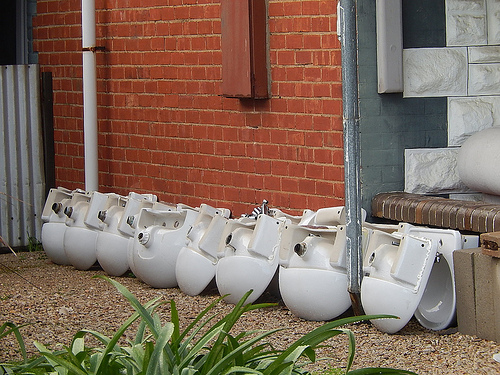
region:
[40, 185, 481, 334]
ceramic sink bowls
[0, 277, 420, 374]
green leaves from a plant in the foreground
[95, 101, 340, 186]
red bricks in a wall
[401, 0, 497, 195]
ceramic molds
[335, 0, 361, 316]
metal drain pipe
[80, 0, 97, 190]
white pvc pipe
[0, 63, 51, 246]
corregated metal sheeting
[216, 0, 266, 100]
weathered red wooden box on the wall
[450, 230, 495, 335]
grey cinder blocks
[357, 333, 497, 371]
gravel covered ground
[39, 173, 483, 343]
a whole lot of sinks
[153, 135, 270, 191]
the wall is made of brick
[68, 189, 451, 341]
the sinks are white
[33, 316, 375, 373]
green plants are growing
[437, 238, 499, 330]
concrete blocks are to the right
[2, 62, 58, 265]
pleated metal fence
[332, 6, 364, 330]
a downspout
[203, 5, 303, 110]
some type of box on the wall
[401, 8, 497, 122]
stone-like blocks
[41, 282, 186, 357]
gravel on the ground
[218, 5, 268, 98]
Rusty red box on side of wall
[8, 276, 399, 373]
Small patch of green grass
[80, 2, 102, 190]
Long white pvc pipe hooked to wall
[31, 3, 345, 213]
Tall brick wall on building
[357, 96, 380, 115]
Small grey brick in wall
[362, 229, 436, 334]
Glass white sink leaning against sink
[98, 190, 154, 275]
White glass sink leaning agains wall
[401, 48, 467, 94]
Large white block in wall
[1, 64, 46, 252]
Small grey metal fencing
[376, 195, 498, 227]
Rusty brick floor on porch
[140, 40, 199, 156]
Red color bricks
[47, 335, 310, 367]
Plants near the wall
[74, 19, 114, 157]
A white color plastic pipe fixed in the wall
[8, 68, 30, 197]
Silver color metal sheet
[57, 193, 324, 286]
White color ceramic washbasin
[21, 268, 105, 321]
Dirt with small size stone near the wall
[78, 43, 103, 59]
Metal clamp with pipe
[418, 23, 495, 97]
White color wall tiles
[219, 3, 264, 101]
A red color box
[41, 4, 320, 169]
Wall madeup of bricks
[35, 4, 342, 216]
wall is made of red brick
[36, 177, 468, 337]
row of white objects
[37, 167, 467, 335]
white objects leaning on the side of the building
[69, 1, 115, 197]
white pole running along the side of the building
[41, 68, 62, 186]
shadow on the building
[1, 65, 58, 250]
white fence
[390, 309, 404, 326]
tip of a leaf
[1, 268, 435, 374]
thin green leaves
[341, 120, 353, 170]
white line on the silver pole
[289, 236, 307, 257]
small black circle